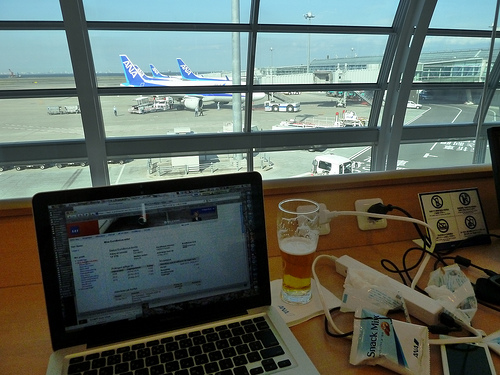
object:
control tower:
[0, 0, 498, 375]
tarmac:
[0, 96, 496, 197]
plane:
[120, 55, 265, 109]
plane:
[176, 57, 251, 81]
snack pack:
[349, 310, 430, 374]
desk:
[0, 165, 498, 373]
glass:
[276, 199, 320, 305]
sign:
[419, 189, 491, 253]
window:
[86, 27, 249, 87]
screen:
[48, 183, 261, 334]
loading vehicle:
[264, 100, 300, 111]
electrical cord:
[380, 206, 445, 290]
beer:
[280, 238, 317, 291]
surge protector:
[335, 254, 442, 326]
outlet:
[355, 198, 388, 230]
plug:
[368, 203, 386, 220]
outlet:
[297, 202, 330, 235]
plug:
[314, 211, 338, 225]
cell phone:
[441, 337, 496, 375]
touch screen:
[444, 344, 490, 374]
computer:
[32, 171, 326, 375]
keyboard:
[67, 314, 290, 375]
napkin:
[270, 276, 340, 330]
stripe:
[265, 106, 297, 108]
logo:
[123, 61, 137, 78]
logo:
[180, 65, 192, 76]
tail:
[120, 55, 144, 85]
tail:
[177, 58, 196, 80]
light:
[303, 11, 314, 71]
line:
[425, 108, 462, 159]